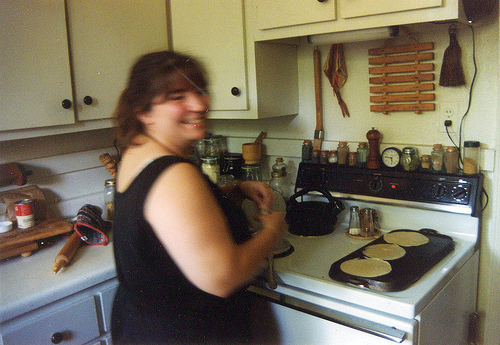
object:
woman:
[111, 50, 286, 344]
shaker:
[359, 207, 375, 236]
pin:
[52, 232, 82, 274]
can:
[14, 199, 36, 229]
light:
[391, 184, 395, 188]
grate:
[364, 37, 437, 115]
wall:
[255, 2, 500, 147]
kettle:
[285, 187, 346, 237]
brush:
[313, 49, 324, 153]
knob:
[452, 187, 467, 199]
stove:
[249, 162, 483, 344]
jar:
[270, 157, 291, 198]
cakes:
[340, 232, 430, 279]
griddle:
[328, 228, 454, 293]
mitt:
[73, 202, 111, 247]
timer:
[381, 147, 403, 168]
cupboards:
[0, 0, 462, 143]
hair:
[109, 48, 207, 158]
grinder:
[366, 126, 382, 169]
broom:
[438, 25, 467, 87]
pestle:
[242, 129, 269, 165]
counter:
[0, 195, 122, 345]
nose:
[185, 95, 208, 111]